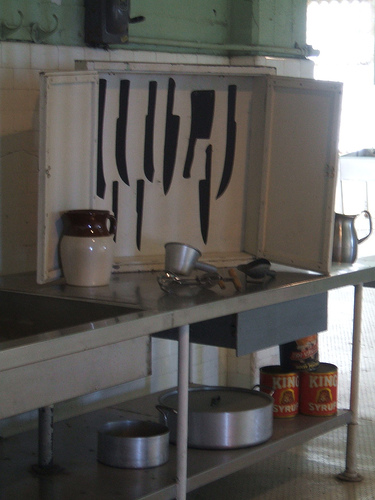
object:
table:
[2, 247, 373, 498]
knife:
[97, 77, 110, 205]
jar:
[58, 194, 118, 292]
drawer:
[202, 290, 329, 365]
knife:
[108, 174, 122, 244]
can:
[299, 360, 340, 420]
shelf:
[0, 385, 350, 499]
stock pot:
[93, 415, 173, 473]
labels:
[257, 331, 338, 420]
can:
[257, 365, 300, 422]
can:
[276, 325, 321, 371]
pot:
[100, 231, 276, 461]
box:
[28, 53, 346, 292]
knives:
[158, 78, 183, 198]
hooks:
[0, 3, 62, 47]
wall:
[0, 1, 308, 74]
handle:
[154, 401, 178, 423]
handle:
[254, 381, 278, 400]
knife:
[215, 84, 240, 198]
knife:
[181, 87, 214, 181]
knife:
[160, 77, 180, 197]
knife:
[135, 177, 143, 252]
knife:
[112, 180, 120, 241]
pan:
[97, 241, 285, 475]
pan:
[97, 418, 174, 472]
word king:
[273, 376, 297, 386]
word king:
[310, 376, 336, 385]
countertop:
[0, 247, 372, 375]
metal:
[327, 203, 374, 266]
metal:
[0, 203, 375, 500]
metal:
[153, 271, 230, 300]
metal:
[147, 378, 283, 450]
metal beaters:
[153, 244, 224, 300]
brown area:
[60, 208, 117, 240]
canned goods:
[299, 362, 340, 421]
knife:
[142, 79, 158, 184]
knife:
[113, 79, 129, 184]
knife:
[195, 143, 212, 244]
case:
[97, 77, 249, 246]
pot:
[153, 379, 281, 454]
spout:
[334, 210, 342, 218]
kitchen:
[0, 2, 373, 500]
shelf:
[54, 261, 361, 316]